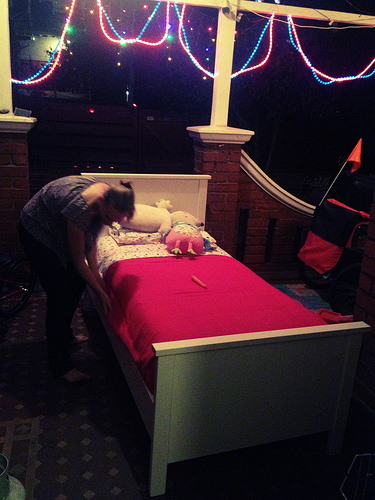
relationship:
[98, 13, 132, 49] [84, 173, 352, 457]
light hanging over bed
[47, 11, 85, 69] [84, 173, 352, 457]
light hanging over bed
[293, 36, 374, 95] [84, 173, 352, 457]
light hanging over bed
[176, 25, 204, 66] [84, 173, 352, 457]
light hanging over bed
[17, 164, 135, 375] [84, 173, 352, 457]
woman making up bed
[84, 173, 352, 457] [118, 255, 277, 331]
bed has comforter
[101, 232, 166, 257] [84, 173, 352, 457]
sheet spread on bed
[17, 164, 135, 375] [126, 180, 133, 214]
woman wearing a ponytail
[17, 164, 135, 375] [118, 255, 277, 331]
woman tucking comforter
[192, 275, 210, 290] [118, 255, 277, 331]
carrot on top of comforter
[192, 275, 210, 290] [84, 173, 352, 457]
carrot on top of bed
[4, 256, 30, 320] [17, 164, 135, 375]
bicycle behind woman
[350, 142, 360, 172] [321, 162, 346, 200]
flag attached to pole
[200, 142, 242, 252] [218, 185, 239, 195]
column made of brick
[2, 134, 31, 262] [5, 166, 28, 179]
column made of brick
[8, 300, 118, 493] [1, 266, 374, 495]
carpet on floor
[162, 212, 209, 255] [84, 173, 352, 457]
toy on top of bed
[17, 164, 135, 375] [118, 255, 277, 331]
woman tucking in comforter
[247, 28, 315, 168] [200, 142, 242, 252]
tree behind column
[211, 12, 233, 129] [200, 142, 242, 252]
post above column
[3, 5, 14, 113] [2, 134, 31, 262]
post above column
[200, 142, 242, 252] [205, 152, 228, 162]
column made of brick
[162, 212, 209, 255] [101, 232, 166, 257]
toy on top of sheet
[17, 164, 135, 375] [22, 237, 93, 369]
woman wearing pants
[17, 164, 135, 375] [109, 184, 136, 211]
woman has hair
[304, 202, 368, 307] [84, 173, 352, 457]
wheel chair next to bed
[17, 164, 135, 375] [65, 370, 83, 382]
woman has foot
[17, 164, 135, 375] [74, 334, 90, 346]
woman has foot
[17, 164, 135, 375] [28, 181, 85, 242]
woman wearing shirt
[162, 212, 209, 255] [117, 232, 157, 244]
toy on top of pillow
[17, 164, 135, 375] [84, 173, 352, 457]
woman making  up bed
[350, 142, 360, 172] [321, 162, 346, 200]
flag on pole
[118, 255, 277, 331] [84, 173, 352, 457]
comforter on top of bed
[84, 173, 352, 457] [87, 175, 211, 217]
bed has headboard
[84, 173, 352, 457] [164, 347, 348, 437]
bed has footboard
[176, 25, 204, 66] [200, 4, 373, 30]
light hanging from beam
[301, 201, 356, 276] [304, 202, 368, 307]
blanket covering wheel chair